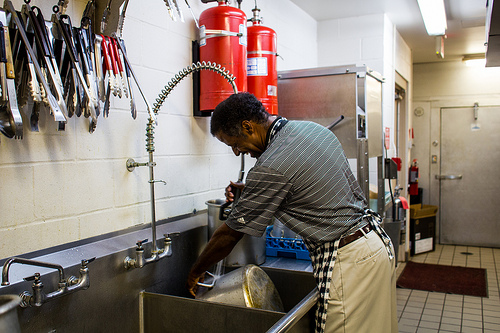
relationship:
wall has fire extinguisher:
[112, 4, 323, 209] [244, 6, 280, 123]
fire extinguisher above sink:
[244, 6, 280, 123] [18, 210, 315, 330]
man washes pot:
[207, 91, 417, 332] [188, 268, 295, 313]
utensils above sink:
[5, 9, 157, 131] [18, 210, 315, 330]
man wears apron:
[207, 91, 417, 332] [307, 244, 333, 332]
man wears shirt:
[207, 91, 417, 332] [226, 123, 376, 237]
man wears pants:
[207, 91, 417, 332] [323, 246, 403, 332]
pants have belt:
[323, 246, 403, 332] [329, 220, 390, 241]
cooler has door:
[428, 99, 498, 251] [436, 107, 498, 247]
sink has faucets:
[18, 210, 315, 330] [1, 227, 188, 303]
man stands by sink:
[207, 91, 417, 332] [18, 210, 315, 330]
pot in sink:
[188, 268, 295, 313] [18, 210, 315, 330]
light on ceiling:
[417, 0, 450, 36] [298, 0, 497, 51]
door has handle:
[436, 107, 498, 247] [439, 175, 459, 183]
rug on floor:
[398, 258, 489, 300] [394, 239, 496, 331]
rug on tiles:
[398, 258, 489, 300] [409, 290, 485, 320]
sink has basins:
[18, 210, 315, 330] [49, 268, 295, 332]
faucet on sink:
[0, 252, 94, 307] [18, 210, 315, 330]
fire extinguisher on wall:
[194, 0, 245, 118] [413, 43, 498, 253]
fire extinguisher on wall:
[244, 6, 280, 123] [413, 43, 498, 253]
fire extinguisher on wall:
[408, 158, 419, 195] [413, 43, 498, 253]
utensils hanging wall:
[45, 9, 98, 131] [0, 1, 321, 264]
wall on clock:
[413, 61, 498, 245] [414, 106, 425, 118]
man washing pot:
[207, 91, 417, 332] [187, 267, 281, 311]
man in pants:
[207, 91, 417, 332] [310, 221, 403, 331]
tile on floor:
[423, 254, 440, 264] [387, 241, 499, 332]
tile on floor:
[452, 259, 467, 267] [387, 241, 499, 332]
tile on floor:
[482, 313, 499, 326] [387, 241, 499, 332]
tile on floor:
[398, 314, 423, 328] [387, 241, 499, 332]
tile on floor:
[422, 306, 442, 316] [387, 241, 499, 332]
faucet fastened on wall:
[125, 61, 260, 269] [0, 1, 321, 264]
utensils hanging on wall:
[45, 9, 98, 131] [0, 1, 321, 264]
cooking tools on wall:
[1, 3, 158, 138] [0, 1, 321, 264]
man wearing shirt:
[207, 91, 417, 332] [224, 118, 374, 247]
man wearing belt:
[207, 91, 417, 332] [325, 218, 381, 251]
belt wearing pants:
[325, 218, 381, 251] [310, 221, 403, 331]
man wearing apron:
[207, 91, 417, 332] [265, 113, 408, 331]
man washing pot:
[207, 91, 417, 332] [188, 268, 295, 313]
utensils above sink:
[45, 9, 98, 131] [9, 206, 341, 316]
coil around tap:
[146, 59, 246, 194] [126, 58, 263, 195]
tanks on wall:
[195, 0, 280, 120] [6, 1, 372, 224]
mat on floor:
[388, 249, 490, 303] [380, 214, 487, 327]